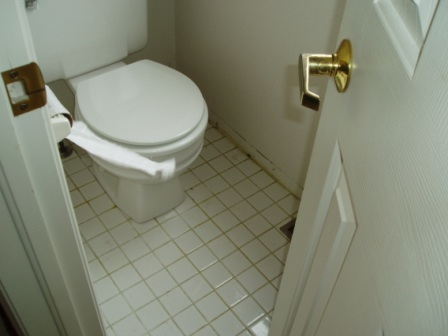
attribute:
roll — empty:
[42, 83, 74, 141]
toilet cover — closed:
[72, 56, 205, 149]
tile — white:
[178, 311, 202, 329]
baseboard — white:
[213, 112, 302, 199]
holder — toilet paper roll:
[49, 112, 70, 144]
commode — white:
[3, 1, 271, 241]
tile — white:
[213, 276, 249, 310]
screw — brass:
[18, 104, 27, 108]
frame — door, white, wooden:
[3, 1, 111, 333]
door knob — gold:
[295, 33, 359, 130]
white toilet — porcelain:
[25, 2, 211, 224]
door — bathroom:
[269, 1, 446, 335]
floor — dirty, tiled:
[91, 182, 279, 330]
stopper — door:
[3, 69, 46, 111]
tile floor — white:
[62, 128, 301, 334]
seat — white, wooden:
[70, 53, 244, 251]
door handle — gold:
[295, 36, 351, 112]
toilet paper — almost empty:
[39, 83, 79, 153]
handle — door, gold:
[239, 24, 343, 84]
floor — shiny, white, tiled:
[52, 121, 299, 334]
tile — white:
[225, 222, 255, 246]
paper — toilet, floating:
[100, 131, 157, 179]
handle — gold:
[299, 37, 356, 109]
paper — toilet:
[71, 126, 168, 176]